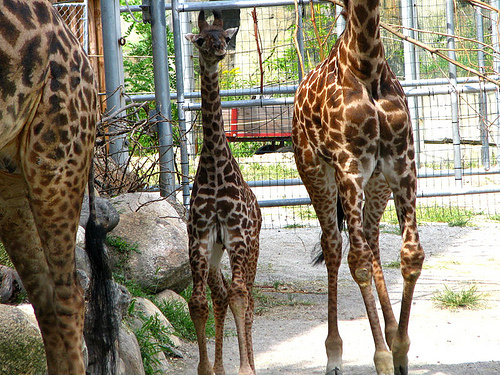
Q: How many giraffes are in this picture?
A: Three.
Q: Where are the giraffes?
A: In an enclosure.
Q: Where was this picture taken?
A: A zoo.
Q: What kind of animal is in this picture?
A: Giraffes.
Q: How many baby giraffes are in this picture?
A: One.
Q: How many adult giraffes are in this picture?
A: Two.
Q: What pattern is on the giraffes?
A: Spots.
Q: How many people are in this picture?
A: Zero.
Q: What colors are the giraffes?
A: Brown and white.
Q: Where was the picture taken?
A: In a zoo.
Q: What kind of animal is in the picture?
A: Giraffes.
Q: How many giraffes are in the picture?
A: 3.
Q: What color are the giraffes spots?
A: Brown.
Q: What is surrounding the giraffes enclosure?
A: A fence.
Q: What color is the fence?
A: Gray.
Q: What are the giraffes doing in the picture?
A: Walking.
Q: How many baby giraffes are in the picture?
A: 1.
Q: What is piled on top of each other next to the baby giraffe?
A: Rocks.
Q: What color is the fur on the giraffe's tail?
A: Black.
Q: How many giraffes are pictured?
A: Three.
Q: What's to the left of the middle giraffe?
A: Boulders.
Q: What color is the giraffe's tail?
A: Black.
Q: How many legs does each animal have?
A: Four.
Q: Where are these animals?
A: Within an enclosure.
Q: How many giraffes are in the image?
A: 3.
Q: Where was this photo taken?
A: A zoo.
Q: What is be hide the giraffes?
A: A fence.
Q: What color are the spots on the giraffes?
A: Brown.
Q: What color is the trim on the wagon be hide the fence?
A: Red.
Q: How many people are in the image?
A: 0.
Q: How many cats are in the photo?
A: 0.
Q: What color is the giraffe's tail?
A: Black.